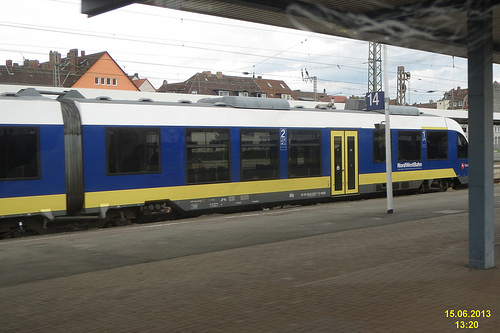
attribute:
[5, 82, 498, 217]
train — yellow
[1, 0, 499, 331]
train station — clear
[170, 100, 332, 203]
train — yellow, blue , white 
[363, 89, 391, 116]
sign — blue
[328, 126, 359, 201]
doors — yellow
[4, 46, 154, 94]
house — orange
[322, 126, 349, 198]
door — yellow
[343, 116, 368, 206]
door — yellow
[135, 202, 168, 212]
wheel — train's wheel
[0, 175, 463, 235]
wheels — train wheels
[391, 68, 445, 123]
tower — metal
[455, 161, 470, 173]
sticker — red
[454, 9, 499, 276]
pole — grey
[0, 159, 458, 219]
stripe — yellow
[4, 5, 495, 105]
sky — cloudy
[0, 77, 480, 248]
train — not moving, blue, white and yellow